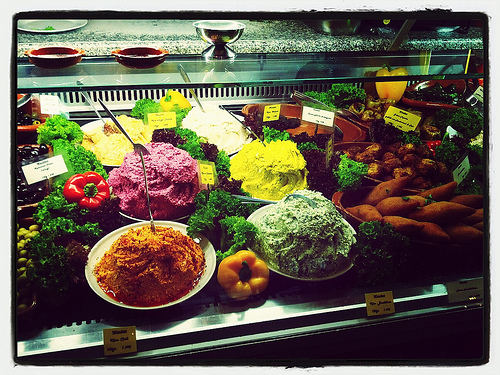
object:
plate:
[17, 19, 88, 33]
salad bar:
[16, 20, 489, 364]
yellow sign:
[200, 164, 214, 186]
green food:
[23, 191, 105, 297]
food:
[416, 221, 451, 243]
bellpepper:
[159, 90, 192, 112]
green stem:
[239, 260, 252, 281]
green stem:
[83, 183, 98, 197]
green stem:
[381, 62, 393, 72]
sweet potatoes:
[446, 222, 484, 242]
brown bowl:
[17, 93, 51, 143]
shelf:
[17, 47, 484, 92]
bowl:
[84, 220, 216, 310]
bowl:
[245, 204, 359, 282]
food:
[382, 216, 426, 236]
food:
[250, 189, 356, 277]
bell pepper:
[217, 250, 269, 302]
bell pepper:
[63, 171, 110, 210]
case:
[11, 17, 491, 363]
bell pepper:
[375, 63, 408, 103]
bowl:
[192, 20, 246, 59]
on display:
[84, 95, 462, 313]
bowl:
[111, 47, 169, 69]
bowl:
[24, 46, 86, 69]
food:
[392, 167, 414, 179]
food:
[366, 143, 382, 159]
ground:
[405, 120, 430, 146]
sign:
[21, 155, 68, 186]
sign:
[301, 106, 335, 128]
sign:
[384, 105, 422, 132]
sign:
[263, 104, 281, 123]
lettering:
[400, 111, 407, 115]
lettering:
[308, 113, 331, 120]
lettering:
[269, 106, 276, 108]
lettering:
[151, 118, 172, 122]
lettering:
[37, 160, 49, 165]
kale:
[186, 188, 261, 260]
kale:
[332, 154, 368, 193]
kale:
[33, 180, 104, 241]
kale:
[176, 128, 204, 160]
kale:
[216, 149, 231, 178]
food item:
[417, 181, 458, 201]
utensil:
[140, 151, 155, 231]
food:
[417, 158, 438, 174]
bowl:
[348, 103, 423, 132]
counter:
[17, 49, 485, 93]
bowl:
[106, 167, 206, 221]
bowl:
[220, 153, 308, 205]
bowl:
[74, 119, 153, 168]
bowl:
[180, 112, 254, 156]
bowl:
[332, 185, 466, 249]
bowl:
[331, 142, 449, 195]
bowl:
[242, 103, 363, 144]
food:
[107, 142, 207, 219]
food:
[229, 139, 309, 201]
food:
[374, 196, 420, 215]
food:
[181, 104, 251, 155]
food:
[346, 204, 384, 222]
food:
[367, 163, 384, 180]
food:
[244, 106, 300, 140]